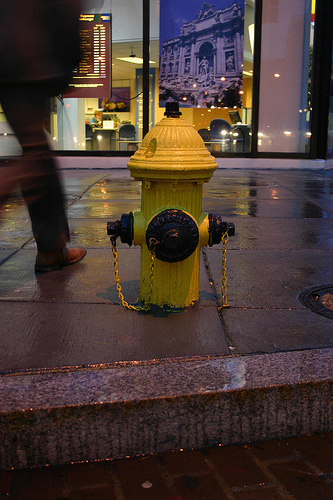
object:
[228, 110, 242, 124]
lap top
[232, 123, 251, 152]
desk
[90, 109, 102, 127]
person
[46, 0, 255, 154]
office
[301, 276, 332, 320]
man hole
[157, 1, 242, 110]
poster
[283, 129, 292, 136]
light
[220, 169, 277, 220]
sidewalk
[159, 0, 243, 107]
banner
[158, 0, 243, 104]
building monument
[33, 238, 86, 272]
boot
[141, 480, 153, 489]
gum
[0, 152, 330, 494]
street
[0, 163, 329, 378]
sidewalk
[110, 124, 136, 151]
chair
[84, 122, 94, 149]
chair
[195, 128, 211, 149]
chair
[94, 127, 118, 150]
desk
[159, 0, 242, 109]
picture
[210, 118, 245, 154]
chair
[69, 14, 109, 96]
informational sign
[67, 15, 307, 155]
store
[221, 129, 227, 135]
headlights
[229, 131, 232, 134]
headlights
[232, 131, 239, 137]
headlights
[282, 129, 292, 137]
headlights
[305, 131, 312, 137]
headlights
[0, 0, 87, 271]
man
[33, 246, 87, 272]
shoe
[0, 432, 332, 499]
bricks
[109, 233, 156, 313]
chain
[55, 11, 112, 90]
sign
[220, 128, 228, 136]
light reflection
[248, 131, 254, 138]
light reflection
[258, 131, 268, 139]
light reflection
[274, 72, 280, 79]
light reflection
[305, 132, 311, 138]
light reflection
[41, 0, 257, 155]
window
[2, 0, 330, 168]
building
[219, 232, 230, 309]
chain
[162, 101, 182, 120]
cap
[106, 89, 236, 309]
fire hydrant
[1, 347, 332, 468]
curb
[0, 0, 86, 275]
image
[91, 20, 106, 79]
business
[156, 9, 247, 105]
rome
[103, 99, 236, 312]
side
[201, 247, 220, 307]
crack